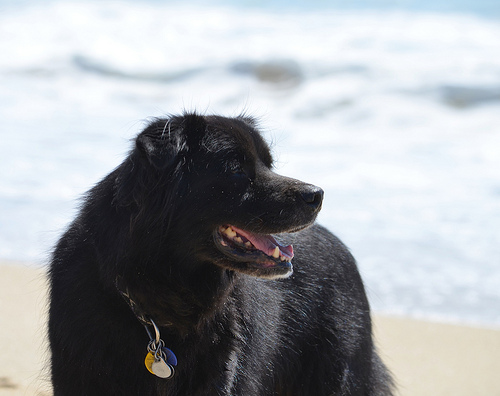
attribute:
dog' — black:
[54, 86, 416, 352]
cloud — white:
[280, 17, 490, 71]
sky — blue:
[209, 2, 489, 17]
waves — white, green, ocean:
[383, 213, 428, 276]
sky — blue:
[389, 0, 499, 21]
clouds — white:
[0, 4, 472, 54]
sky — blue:
[211, 0, 401, 7]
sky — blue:
[2, 2, 497, 121]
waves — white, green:
[307, 37, 475, 145]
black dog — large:
[48, 112, 393, 391]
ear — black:
[135, 112, 193, 169]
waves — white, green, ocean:
[64, 41, 499, 168]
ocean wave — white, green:
[410, 51, 498, 107]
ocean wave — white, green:
[196, 46, 362, 118]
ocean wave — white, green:
[20, 40, 178, 82]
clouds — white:
[287, 21, 462, 72]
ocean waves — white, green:
[0, 36, 345, 110]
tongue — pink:
[227, 225, 292, 259]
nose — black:
[295, 184, 322, 209]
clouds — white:
[289, 12, 486, 92]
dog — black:
[39, 97, 399, 394]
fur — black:
[258, 291, 340, 360]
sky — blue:
[68, 9, 392, 85]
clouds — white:
[294, 0, 483, 87]